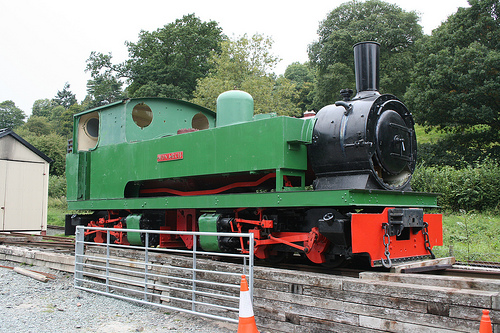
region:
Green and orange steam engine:
[43, 42, 473, 304]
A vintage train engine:
[21, 15, 493, 225]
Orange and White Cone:
[218, 261, 273, 328]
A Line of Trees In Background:
[62, 5, 335, 73]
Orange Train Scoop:
[322, 181, 468, 308]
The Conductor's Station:
[55, 80, 225, 225]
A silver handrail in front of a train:
[50, 175, 297, 327]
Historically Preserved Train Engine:
[52, 65, 457, 295]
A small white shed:
[2, 98, 65, 295]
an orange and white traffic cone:
[230, 269, 262, 331]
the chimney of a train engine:
[347, 35, 385, 95]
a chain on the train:
[374, 217, 394, 275]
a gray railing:
[66, 221, 261, 328]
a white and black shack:
[0, 120, 54, 237]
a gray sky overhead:
[1, 0, 496, 127]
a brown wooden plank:
[11, 262, 51, 284]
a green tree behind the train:
[301, 0, 431, 119]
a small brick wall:
[0, 227, 499, 329]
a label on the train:
[154, 147, 187, 166]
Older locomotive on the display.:
[64, 40, 456, 272]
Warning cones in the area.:
[229, 268, 494, 330]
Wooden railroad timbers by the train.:
[2, 236, 494, 332]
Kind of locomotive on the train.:
[152, 146, 185, 163]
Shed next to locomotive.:
[1, 121, 57, 241]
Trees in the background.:
[11, 3, 498, 258]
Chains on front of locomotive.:
[378, 211, 444, 268]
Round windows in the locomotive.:
[70, 96, 221, 143]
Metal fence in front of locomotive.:
[70, 222, 266, 332]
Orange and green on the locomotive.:
[61, 101, 451, 263]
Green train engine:
[65, 110, 455, 275]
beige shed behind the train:
[5, 131, 51, 235]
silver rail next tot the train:
[69, 221, 274, 326]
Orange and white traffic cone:
[232, 280, 252, 331]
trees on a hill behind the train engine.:
[64, 0, 496, 180]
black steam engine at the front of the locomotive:
[310, 45, 424, 196]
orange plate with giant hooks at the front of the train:
[348, 210, 461, 274]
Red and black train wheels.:
[76, 213, 345, 257]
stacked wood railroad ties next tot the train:
[59, 257, 498, 332]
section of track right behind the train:
[0, 232, 82, 249]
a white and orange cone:
[221, 273, 271, 321]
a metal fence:
[98, 247, 190, 295]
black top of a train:
[351, 30, 388, 89]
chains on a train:
[376, 215, 441, 271]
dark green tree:
[142, 27, 214, 84]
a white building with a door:
[0, 152, 46, 232]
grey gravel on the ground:
[1, 297, 76, 327]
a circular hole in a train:
[118, 100, 163, 133]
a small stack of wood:
[321, 287, 413, 332]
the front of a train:
[365, 115, 417, 171]